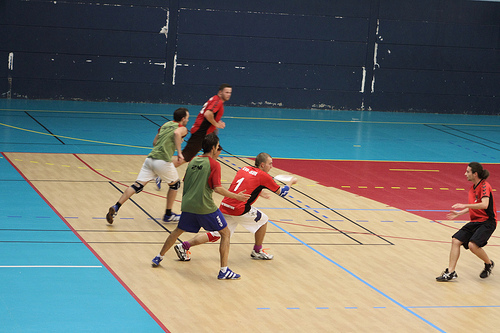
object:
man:
[173, 84, 234, 170]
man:
[218, 152, 299, 263]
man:
[105, 106, 190, 224]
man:
[152, 133, 252, 278]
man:
[434, 161, 497, 284]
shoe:
[217, 267, 242, 281]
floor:
[0, 99, 497, 331]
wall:
[0, 0, 498, 114]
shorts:
[177, 211, 227, 235]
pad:
[169, 179, 184, 191]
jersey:
[219, 165, 282, 213]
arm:
[211, 160, 254, 201]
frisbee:
[273, 172, 291, 184]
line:
[0, 152, 173, 331]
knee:
[468, 241, 478, 250]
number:
[234, 175, 247, 191]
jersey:
[191, 93, 223, 136]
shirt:
[148, 118, 190, 161]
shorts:
[210, 203, 270, 235]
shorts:
[452, 216, 497, 250]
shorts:
[137, 159, 179, 185]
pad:
[132, 178, 145, 192]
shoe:
[480, 260, 497, 278]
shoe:
[435, 268, 459, 282]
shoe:
[162, 211, 182, 222]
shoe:
[105, 204, 120, 226]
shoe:
[152, 254, 165, 267]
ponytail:
[480, 169, 490, 180]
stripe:
[223, 269, 232, 279]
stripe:
[227, 272, 233, 279]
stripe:
[230, 272, 235, 280]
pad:
[279, 186, 290, 198]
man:
[217, 153, 290, 273]